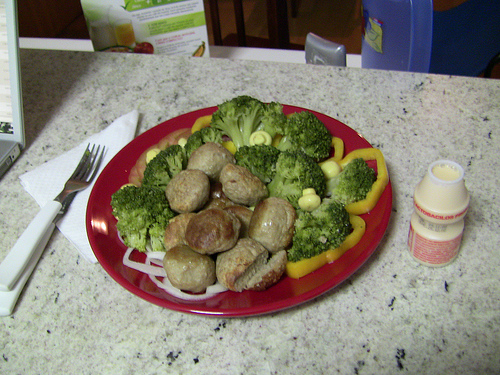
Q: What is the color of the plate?
A: Red.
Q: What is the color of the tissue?
A: White.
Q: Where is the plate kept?
A: On the table.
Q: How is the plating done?
A: With lots of broccoli.